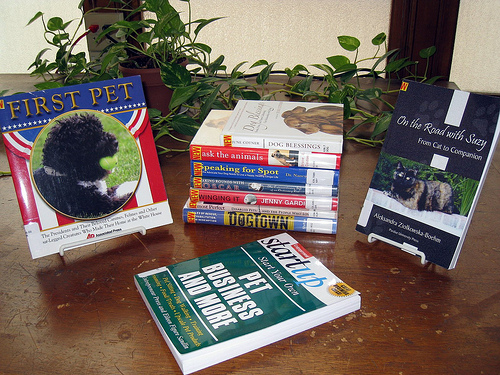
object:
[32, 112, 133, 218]
dog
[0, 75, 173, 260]
book cover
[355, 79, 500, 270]
book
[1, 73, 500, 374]
table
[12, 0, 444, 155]
leaves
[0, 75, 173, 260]
book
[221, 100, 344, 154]
book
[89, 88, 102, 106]
letter p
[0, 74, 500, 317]
ground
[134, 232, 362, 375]
book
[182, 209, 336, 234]
book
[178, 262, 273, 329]
words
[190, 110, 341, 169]
book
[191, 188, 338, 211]
book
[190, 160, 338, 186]
book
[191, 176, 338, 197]
book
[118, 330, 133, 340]
spot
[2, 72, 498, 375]
surface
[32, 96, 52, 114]
letter "r"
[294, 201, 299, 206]
letter "r"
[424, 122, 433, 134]
letter "r"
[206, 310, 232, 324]
letter "r"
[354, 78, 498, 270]
book cover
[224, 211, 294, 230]
yellow spine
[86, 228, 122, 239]
book stand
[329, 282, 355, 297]
stickers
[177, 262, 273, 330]
labels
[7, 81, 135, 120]
top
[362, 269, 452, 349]
marks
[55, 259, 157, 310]
scratches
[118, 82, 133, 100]
letter t